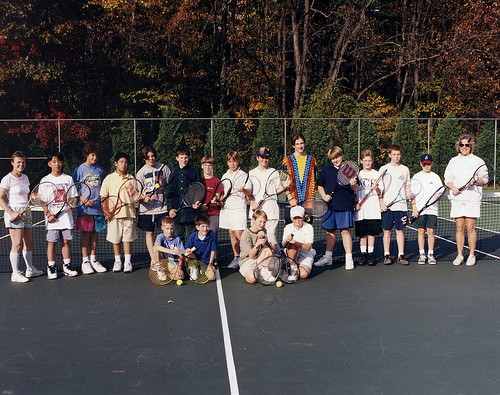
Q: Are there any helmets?
A: No, there are no helmets.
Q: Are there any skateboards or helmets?
A: No, there are no helmets or skateboards.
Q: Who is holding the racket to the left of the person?
A: The boy is holding the racket.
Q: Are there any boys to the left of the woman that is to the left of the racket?
A: Yes, there is a boy to the left of the woman.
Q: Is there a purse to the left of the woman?
A: No, there is a boy to the left of the woman.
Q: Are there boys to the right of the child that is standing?
A: Yes, there is a boy to the right of the kid.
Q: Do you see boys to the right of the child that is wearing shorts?
A: Yes, there is a boy to the right of the child.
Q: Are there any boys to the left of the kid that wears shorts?
A: No, the boy is to the right of the kid.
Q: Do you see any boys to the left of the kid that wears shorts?
A: No, the boy is to the right of the kid.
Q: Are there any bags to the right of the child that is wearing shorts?
A: No, there is a boy to the right of the kid.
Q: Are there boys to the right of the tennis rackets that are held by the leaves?
A: Yes, there is a boy to the right of the tennis rackets.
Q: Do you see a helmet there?
A: No, there are no helmets.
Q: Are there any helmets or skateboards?
A: No, there are no helmets or skateboards.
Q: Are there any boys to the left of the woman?
A: Yes, there is a boy to the left of the woman.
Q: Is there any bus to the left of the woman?
A: No, there is a boy to the left of the woman.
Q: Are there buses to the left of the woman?
A: No, there is a boy to the left of the woman.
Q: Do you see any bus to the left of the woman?
A: No, there is a boy to the left of the woman.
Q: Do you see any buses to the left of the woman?
A: No, there is a boy to the left of the woman.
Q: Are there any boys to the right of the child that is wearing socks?
A: Yes, there is a boy to the right of the child.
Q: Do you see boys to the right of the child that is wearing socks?
A: Yes, there is a boy to the right of the child.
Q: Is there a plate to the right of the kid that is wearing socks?
A: No, there is a boy to the right of the child.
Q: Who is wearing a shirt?
A: The boy is wearing a shirt.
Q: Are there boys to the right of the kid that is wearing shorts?
A: Yes, there is a boy to the right of the child.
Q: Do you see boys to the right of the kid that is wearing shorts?
A: Yes, there is a boy to the right of the child.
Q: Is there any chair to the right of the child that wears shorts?
A: No, there is a boy to the right of the kid.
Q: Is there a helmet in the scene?
A: No, there are no helmets.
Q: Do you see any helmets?
A: No, there are no helmets.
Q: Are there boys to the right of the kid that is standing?
A: Yes, there is a boy to the right of the kid.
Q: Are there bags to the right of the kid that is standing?
A: No, there is a boy to the right of the kid.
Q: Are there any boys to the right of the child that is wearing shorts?
A: Yes, there is a boy to the right of the kid.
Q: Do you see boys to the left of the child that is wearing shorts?
A: No, the boy is to the right of the child.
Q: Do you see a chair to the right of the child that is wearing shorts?
A: No, there is a boy to the right of the kid.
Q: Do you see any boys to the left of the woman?
A: Yes, there is a boy to the left of the woman.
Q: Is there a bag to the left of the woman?
A: No, there is a boy to the left of the woman.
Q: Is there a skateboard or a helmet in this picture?
A: No, there are no helmets or skateboards.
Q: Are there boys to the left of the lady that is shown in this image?
A: Yes, there is a boy to the left of the lady.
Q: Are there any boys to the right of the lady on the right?
A: No, the boy is to the left of the lady.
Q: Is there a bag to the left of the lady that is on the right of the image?
A: No, there is a boy to the left of the lady.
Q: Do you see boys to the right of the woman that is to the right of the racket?
A: Yes, there is a boy to the right of the woman.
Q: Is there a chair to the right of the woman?
A: No, there is a boy to the right of the woman.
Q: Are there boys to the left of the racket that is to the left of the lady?
A: Yes, there is a boy to the left of the racket.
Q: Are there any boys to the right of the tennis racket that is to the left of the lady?
A: No, the boy is to the left of the racket.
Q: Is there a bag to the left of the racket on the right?
A: No, there is a boy to the left of the racket.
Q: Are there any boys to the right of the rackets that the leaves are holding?
A: Yes, there is a boy to the right of the rackets.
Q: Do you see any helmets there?
A: No, there are no helmets.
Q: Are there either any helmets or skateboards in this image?
A: No, there are no helmets or skateboards.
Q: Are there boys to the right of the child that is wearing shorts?
A: Yes, there is a boy to the right of the child.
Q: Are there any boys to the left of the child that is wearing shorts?
A: No, the boy is to the right of the kid.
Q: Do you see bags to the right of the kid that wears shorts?
A: No, there is a boy to the right of the child.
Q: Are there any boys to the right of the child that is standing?
A: Yes, there is a boy to the right of the child.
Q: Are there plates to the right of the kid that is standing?
A: No, there is a boy to the right of the kid.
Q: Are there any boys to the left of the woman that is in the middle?
A: Yes, there is a boy to the left of the woman.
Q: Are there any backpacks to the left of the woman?
A: No, there is a boy to the left of the woman.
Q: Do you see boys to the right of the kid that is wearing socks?
A: Yes, there is a boy to the right of the kid.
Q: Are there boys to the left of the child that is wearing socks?
A: No, the boy is to the right of the child.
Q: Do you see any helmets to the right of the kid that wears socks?
A: No, there is a boy to the right of the child.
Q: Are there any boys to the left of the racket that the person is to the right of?
A: Yes, there is a boy to the left of the tennis racket.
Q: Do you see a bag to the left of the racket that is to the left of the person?
A: No, there is a boy to the left of the tennis racket.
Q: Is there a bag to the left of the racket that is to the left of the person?
A: No, there is a boy to the left of the tennis racket.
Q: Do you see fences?
A: Yes, there is a fence.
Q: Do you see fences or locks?
A: Yes, there is a fence.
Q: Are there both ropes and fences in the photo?
A: No, there is a fence but no ropes.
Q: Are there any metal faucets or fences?
A: Yes, there is a metal fence.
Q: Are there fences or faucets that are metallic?
A: Yes, the fence is metallic.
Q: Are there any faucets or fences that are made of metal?
A: Yes, the fence is made of metal.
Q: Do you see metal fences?
A: Yes, there is a metal fence.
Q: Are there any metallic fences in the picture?
A: Yes, there is a metal fence.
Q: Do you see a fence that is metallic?
A: Yes, there is a fence that is metallic.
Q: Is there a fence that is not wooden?
A: Yes, there is a metallic fence.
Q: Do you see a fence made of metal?
A: Yes, there is a fence that is made of metal.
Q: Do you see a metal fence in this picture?
A: Yes, there is a fence that is made of metal.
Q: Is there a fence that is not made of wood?
A: Yes, there is a fence that is made of metal.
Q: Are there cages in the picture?
A: No, there are no cages.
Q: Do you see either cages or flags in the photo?
A: No, there are no cages or flags.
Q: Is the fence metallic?
A: Yes, the fence is metallic.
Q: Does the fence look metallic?
A: Yes, the fence is metallic.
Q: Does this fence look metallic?
A: Yes, the fence is metallic.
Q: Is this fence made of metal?
A: Yes, the fence is made of metal.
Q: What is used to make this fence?
A: The fence is made of metal.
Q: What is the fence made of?
A: The fence is made of metal.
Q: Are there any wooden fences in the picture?
A: No, there is a fence but it is metallic.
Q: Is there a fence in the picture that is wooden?
A: No, there is a fence but it is metallic.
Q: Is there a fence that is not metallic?
A: No, there is a fence but it is metallic.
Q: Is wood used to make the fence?
A: No, the fence is made of metal.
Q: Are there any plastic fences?
A: No, there is a fence but it is made of metal.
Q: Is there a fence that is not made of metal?
A: No, there is a fence but it is made of metal.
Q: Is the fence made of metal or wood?
A: The fence is made of metal.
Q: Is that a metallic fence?
A: Yes, that is a metallic fence.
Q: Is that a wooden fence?
A: No, that is a metallic fence.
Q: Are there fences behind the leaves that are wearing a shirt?
A: Yes, there is a fence behind the leaves.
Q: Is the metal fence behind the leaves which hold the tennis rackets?
A: Yes, the fence is behind the leaves.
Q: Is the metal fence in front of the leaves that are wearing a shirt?
A: No, the fence is behind the leaves.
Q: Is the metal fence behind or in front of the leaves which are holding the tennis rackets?
A: The fence is behind the leaves.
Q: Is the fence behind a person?
A: No, the fence is in front of a person.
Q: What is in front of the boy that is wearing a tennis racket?
A: The fence is in front of the boy.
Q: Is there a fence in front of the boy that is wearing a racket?
A: Yes, there is a fence in front of the boy.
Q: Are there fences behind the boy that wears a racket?
A: No, the fence is in front of the boy.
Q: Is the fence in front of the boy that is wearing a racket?
A: Yes, the fence is in front of the boy.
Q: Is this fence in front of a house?
A: No, the fence is in front of the boy.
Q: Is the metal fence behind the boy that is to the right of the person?
A: No, the fence is in front of the boy.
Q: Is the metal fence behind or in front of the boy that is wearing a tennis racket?
A: The fence is in front of the boy.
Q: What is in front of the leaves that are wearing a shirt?
A: The fence is in front of the leaves.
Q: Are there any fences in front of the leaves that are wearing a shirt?
A: Yes, there is a fence in front of the leaves.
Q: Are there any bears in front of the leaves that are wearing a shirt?
A: No, there is a fence in front of the leaves.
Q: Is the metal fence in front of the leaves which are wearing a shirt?
A: Yes, the fence is in front of the leaves.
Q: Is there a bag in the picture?
A: No, there are no bags.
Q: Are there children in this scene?
A: Yes, there is a child.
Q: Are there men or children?
A: Yes, there is a child.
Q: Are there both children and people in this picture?
A: Yes, there are both a child and people.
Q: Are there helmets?
A: No, there are no helmets.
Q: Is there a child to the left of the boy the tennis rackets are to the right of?
A: Yes, there is a child to the left of the boy.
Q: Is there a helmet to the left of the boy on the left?
A: No, there is a child to the left of the boy.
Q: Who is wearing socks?
A: The child is wearing socks.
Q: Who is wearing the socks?
A: The child is wearing socks.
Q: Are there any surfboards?
A: No, there are no surfboards.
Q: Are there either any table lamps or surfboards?
A: No, there are no surfboards or table lamps.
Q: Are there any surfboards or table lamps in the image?
A: No, there are no surfboards or table lamps.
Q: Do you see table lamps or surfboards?
A: No, there are no surfboards or table lamps.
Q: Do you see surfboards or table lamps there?
A: No, there are no surfboards or table lamps.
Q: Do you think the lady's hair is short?
A: Yes, the hair is short.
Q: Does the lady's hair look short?
A: Yes, the hair is short.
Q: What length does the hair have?
A: The hair has short length.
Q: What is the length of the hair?
A: The hair is short.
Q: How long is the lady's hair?
A: The hair is short.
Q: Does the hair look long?
A: No, the hair is short.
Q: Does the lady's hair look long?
A: No, the hair is short.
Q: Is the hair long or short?
A: The hair is short.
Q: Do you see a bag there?
A: No, there are no bags.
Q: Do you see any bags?
A: No, there are no bags.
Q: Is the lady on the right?
A: Yes, the lady is on the right of the image.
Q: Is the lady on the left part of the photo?
A: No, the lady is on the right of the image.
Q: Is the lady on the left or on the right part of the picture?
A: The lady is on the right of the image.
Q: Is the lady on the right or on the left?
A: The lady is on the right of the image.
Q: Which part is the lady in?
A: The lady is on the right of the image.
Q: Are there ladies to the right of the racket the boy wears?
A: Yes, there is a lady to the right of the tennis racket.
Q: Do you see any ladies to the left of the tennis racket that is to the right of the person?
A: No, the lady is to the right of the tennis racket.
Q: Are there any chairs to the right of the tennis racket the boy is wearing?
A: No, there is a lady to the right of the tennis racket.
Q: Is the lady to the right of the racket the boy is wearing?
A: Yes, the lady is to the right of the tennis racket.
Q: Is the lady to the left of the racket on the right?
A: No, the lady is to the right of the tennis racket.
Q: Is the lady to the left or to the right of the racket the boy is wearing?
A: The lady is to the right of the racket.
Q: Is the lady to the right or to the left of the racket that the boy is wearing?
A: The lady is to the right of the racket.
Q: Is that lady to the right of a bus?
A: No, the lady is to the right of a person.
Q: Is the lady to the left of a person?
A: No, the lady is to the right of a person.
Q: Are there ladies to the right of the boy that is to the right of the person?
A: Yes, there is a lady to the right of the boy.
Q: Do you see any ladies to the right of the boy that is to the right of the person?
A: Yes, there is a lady to the right of the boy.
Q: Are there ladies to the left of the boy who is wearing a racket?
A: No, the lady is to the right of the boy.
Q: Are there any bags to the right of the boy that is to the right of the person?
A: No, there is a lady to the right of the boy.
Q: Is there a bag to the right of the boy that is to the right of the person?
A: No, there is a lady to the right of the boy.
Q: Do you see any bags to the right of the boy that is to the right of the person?
A: No, there is a lady to the right of the boy.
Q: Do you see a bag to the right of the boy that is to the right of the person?
A: No, there is a lady to the right of the boy.